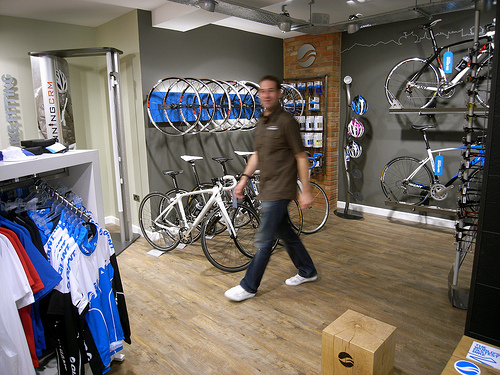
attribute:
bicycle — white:
[135, 170, 267, 278]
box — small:
[433, 332, 497, 373]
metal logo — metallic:
[279, 41, 340, 201]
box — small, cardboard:
[321, 310, 396, 373]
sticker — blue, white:
[445, 353, 498, 372]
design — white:
[338, 14, 495, 49]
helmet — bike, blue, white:
[348, 102, 363, 120]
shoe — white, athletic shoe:
[198, 279, 297, 321]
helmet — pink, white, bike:
[344, 110, 364, 142]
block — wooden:
[321, 309, 422, 367]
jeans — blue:
[252, 200, 317, 292]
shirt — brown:
[252, 110, 305, 202]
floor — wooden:
[106, 204, 473, 372]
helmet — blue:
[341, 118, 366, 138]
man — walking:
[254, 74, 319, 257]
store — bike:
[119, 15, 481, 346]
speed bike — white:
[123, 155, 276, 289]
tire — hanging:
[145, 75, 201, 135]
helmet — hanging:
[351, 93, 368, 116]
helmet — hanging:
[346, 116, 365, 139]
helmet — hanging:
[343, 137, 362, 159]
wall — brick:
[282, 29, 340, 213]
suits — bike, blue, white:
[42, 205, 132, 373]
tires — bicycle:
[146, 77, 305, 136]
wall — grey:
[138, 10, 284, 241]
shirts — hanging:
[44, 203, 131, 373]